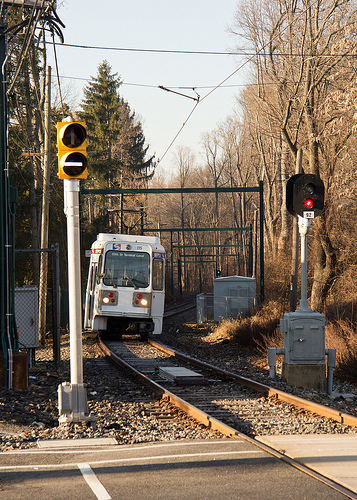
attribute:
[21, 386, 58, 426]
pepples — small, gray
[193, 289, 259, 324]
fence — chain link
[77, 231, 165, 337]
train — white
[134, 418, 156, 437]
pepples — grey, small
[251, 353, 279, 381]
pepples — grey, small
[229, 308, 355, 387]
grass — high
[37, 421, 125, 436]
pebbles — gray, small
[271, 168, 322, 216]
signal — red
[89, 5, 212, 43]
sky — clear blue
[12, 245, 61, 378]
fence — chain link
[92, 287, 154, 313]
headlights — on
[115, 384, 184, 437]
gravel — gray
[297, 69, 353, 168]
trees — bare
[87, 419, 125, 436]
pebbles — grey, small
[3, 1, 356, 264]
wooded area — large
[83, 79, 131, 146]
tree — tall, large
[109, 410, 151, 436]
pebbles — small, grey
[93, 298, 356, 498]
railroad tracks — steel, rusted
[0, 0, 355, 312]
woods — large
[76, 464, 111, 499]
lines — white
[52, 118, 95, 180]
signal — yellow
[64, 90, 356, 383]
area — wooded